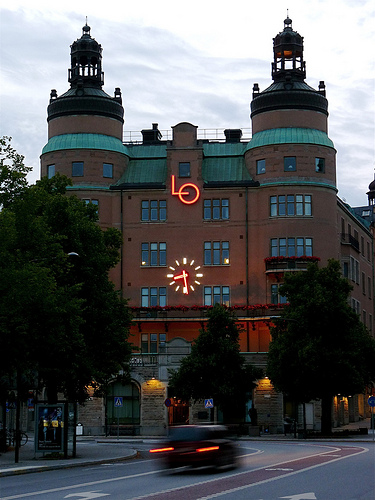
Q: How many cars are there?
A: 1.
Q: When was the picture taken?
A: 8:29.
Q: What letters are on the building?
A: LO.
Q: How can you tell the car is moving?
A: It is blurry.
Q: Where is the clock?
A: On the building.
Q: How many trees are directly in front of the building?
A: 2.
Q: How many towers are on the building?
A: 2.